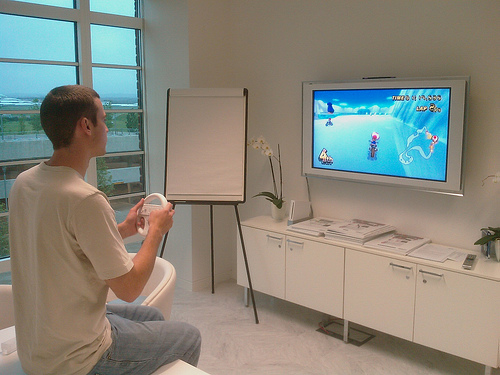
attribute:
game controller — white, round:
[134, 194, 176, 233]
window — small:
[90, 27, 146, 237]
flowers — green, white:
[248, 127, 283, 208]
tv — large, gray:
[302, 78, 467, 195]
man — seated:
[8, 82, 206, 375]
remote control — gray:
[460, 251, 476, 271]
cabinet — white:
[233, 216, 499, 374]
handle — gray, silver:
[267, 229, 282, 243]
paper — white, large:
[159, 84, 250, 202]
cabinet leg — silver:
[243, 289, 254, 305]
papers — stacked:
[293, 211, 456, 270]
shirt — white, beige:
[8, 162, 134, 374]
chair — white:
[107, 251, 176, 324]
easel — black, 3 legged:
[150, 86, 267, 328]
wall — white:
[189, 4, 499, 327]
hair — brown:
[38, 83, 103, 146]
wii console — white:
[287, 196, 309, 222]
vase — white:
[271, 203, 286, 223]